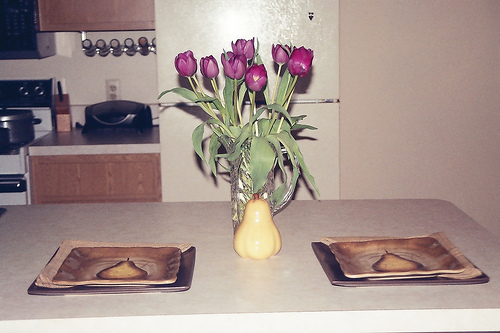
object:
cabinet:
[27, 151, 161, 202]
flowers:
[194, 53, 225, 88]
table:
[3, 193, 499, 331]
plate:
[25, 237, 198, 299]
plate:
[311, 227, 490, 288]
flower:
[242, 57, 276, 145]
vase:
[218, 131, 289, 251]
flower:
[219, 47, 246, 132]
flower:
[271, 41, 294, 69]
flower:
[230, 33, 259, 61]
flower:
[173, 47, 199, 80]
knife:
[53, 80, 70, 105]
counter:
[32, 101, 160, 151]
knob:
[33, 83, 46, 98]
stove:
[1, 72, 57, 202]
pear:
[96, 253, 150, 287]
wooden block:
[50, 92, 78, 135]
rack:
[78, 33, 158, 60]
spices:
[81, 39, 94, 50]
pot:
[3, 104, 40, 148]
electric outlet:
[102, 77, 121, 103]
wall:
[60, 34, 159, 105]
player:
[82, 98, 157, 137]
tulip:
[287, 42, 319, 83]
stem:
[172, 83, 212, 126]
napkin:
[54, 244, 186, 286]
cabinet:
[36, 2, 155, 31]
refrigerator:
[152, 0, 341, 201]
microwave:
[0, 3, 58, 62]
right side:
[447, 5, 499, 311]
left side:
[3, 2, 35, 332]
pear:
[370, 244, 425, 273]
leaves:
[248, 136, 279, 193]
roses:
[288, 46, 317, 103]